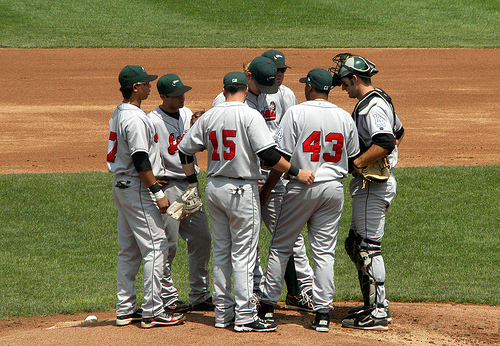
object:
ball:
[84, 313, 100, 326]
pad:
[350, 229, 383, 270]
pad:
[345, 231, 356, 265]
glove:
[114, 180, 135, 189]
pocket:
[116, 178, 132, 193]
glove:
[167, 185, 203, 221]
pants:
[114, 175, 168, 320]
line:
[137, 177, 159, 320]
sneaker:
[141, 309, 188, 327]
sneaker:
[114, 316, 138, 324]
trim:
[160, 311, 180, 321]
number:
[303, 129, 345, 163]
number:
[206, 129, 237, 163]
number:
[169, 131, 182, 157]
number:
[110, 127, 118, 171]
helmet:
[330, 52, 378, 83]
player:
[331, 54, 405, 330]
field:
[3, 2, 500, 344]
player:
[258, 68, 358, 331]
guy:
[179, 73, 314, 331]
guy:
[148, 73, 213, 317]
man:
[107, 67, 187, 324]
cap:
[120, 64, 160, 88]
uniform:
[331, 94, 404, 320]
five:
[219, 129, 238, 159]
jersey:
[177, 99, 278, 179]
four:
[304, 129, 322, 161]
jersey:
[277, 99, 362, 182]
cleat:
[235, 317, 277, 333]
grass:
[1, 1, 499, 318]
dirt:
[3, 47, 499, 344]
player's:
[351, 158, 391, 192]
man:
[213, 55, 314, 311]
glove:
[231, 186, 246, 198]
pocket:
[228, 190, 247, 205]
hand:
[353, 153, 368, 181]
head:
[329, 50, 377, 99]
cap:
[299, 67, 334, 93]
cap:
[251, 57, 279, 95]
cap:
[224, 70, 248, 90]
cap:
[158, 73, 191, 97]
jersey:
[147, 106, 201, 179]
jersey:
[109, 103, 164, 179]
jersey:
[351, 88, 405, 179]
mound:
[3, 299, 499, 345]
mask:
[328, 53, 352, 87]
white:
[322, 84, 337, 91]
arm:
[251, 109, 299, 189]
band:
[148, 181, 162, 195]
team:
[96, 51, 403, 332]